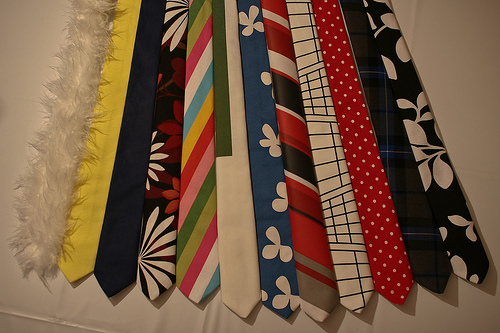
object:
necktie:
[310, 1, 411, 306]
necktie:
[364, 0, 490, 285]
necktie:
[258, 1, 339, 325]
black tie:
[92, 2, 165, 298]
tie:
[174, 0, 222, 302]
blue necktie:
[235, 5, 301, 321]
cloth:
[196, 317, 283, 331]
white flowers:
[236, 4, 263, 35]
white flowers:
[261, 65, 275, 103]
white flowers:
[259, 122, 281, 162]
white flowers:
[271, 180, 290, 215]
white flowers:
[259, 225, 293, 262]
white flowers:
[271, 274, 300, 314]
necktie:
[138, 0, 187, 299]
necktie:
[311, 6, 415, 306]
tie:
[289, 2, 397, 313]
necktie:
[11, 1, 145, 286]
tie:
[234, 0, 298, 317]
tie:
[259, 1, 339, 322]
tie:
[210, 1, 266, 317]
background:
[0, 0, 499, 327]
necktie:
[173, 2, 219, 304]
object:
[436, 213, 479, 285]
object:
[393, 84, 453, 194]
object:
[358, 3, 412, 84]